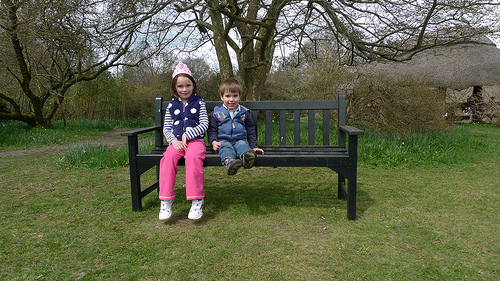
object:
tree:
[0, 2, 157, 140]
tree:
[185, 1, 482, 95]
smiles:
[174, 91, 238, 108]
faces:
[165, 70, 252, 108]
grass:
[1, 105, 498, 280]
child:
[159, 62, 214, 218]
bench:
[265, 98, 362, 222]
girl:
[155, 57, 217, 227]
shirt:
[162, 97, 208, 141]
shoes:
[150, 198, 204, 220]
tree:
[3, 2, 490, 61]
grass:
[372, 137, 492, 265]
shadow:
[151, 167, 376, 225]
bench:
[121, 93, 364, 218]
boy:
[207, 80, 266, 175]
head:
[168, 60, 255, 109]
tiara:
[169, 62, 193, 78]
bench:
[268, 90, 387, 227]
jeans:
[217, 138, 258, 172]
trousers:
[156, 141, 200, 198]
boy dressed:
[207, 82, 266, 177]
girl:
[156, 61, 208, 223]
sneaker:
[185, 199, 205, 220]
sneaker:
[157, 201, 174, 218]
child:
[156, 60, 209, 222]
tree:
[69, 13, 407, 98]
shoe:
[240, 147, 257, 169]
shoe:
[226, 157, 241, 175]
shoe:
[188, 198, 206, 219]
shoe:
[158, 200, 173, 220]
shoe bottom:
[243, 153, 254, 169]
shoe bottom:
[228, 160, 239, 176]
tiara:
[169, 56, 191, 78]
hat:
[168, 60, 195, 80]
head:
[169, 72, 198, 99]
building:
[397, 36, 497, 134]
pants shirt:
[154, 94, 210, 200]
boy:
[207, 78, 271, 177]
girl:
[157, 51, 210, 223]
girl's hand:
[156, 51, 209, 153]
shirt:
[210, 104, 253, 141]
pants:
[155, 139, 206, 200]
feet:
[151, 197, 208, 220]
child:
[208, 80, 264, 176]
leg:
[234, 137, 257, 168]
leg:
[219, 139, 242, 175]